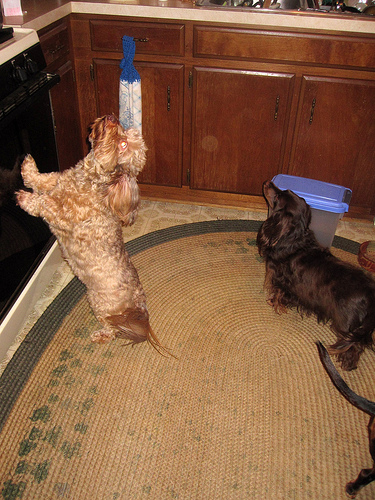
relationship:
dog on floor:
[13, 111, 179, 359] [1, 193, 361, 496]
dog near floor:
[13, 111, 179, 359] [1, 193, 361, 496]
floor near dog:
[1, 193, 361, 496] [13, 111, 179, 359]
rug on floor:
[1, 218, 363, 490] [1, 193, 361, 496]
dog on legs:
[13, 111, 179, 359] [93, 310, 116, 342]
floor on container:
[1, 193, 361, 496] [269, 173, 352, 250]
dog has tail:
[17, 111, 149, 344] [106, 305, 172, 358]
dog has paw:
[17, 111, 149, 344] [20, 152, 41, 187]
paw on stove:
[20, 152, 41, 187] [1, 24, 58, 324]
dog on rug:
[256, 180, 360, 370] [1, 218, 363, 490]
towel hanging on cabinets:
[116, 33, 141, 129] [39, 2, 360, 219]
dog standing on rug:
[17, 111, 149, 344] [1, 218, 363, 490]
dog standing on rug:
[256, 180, 360, 370] [1, 218, 363, 490]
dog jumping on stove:
[17, 111, 149, 344] [1, 24, 58, 324]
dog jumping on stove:
[17, 111, 149, 344] [1, 24, 67, 326]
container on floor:
[269, 173, 352, 250] [1, 193, 361, 496]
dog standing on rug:
[311, 338, 363, 496] [1, 218, 363, 490]